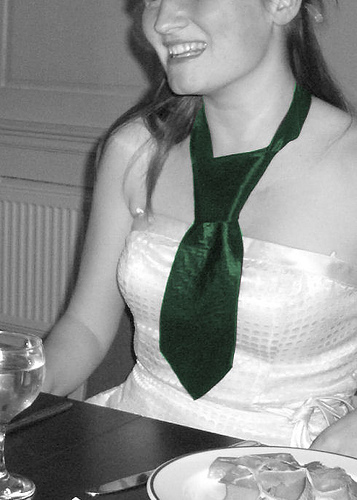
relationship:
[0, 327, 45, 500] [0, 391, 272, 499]
glass on table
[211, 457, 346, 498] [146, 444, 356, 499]
food on plate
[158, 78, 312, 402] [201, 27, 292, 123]
tie around neck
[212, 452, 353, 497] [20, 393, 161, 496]
meat on table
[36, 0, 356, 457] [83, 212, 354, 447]
female wearing a dress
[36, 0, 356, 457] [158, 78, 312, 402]
female wearing a tie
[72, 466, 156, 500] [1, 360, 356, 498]
butter knife on table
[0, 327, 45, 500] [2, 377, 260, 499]
glass on table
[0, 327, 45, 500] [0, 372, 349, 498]
glass on table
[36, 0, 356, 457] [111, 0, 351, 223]
female with hair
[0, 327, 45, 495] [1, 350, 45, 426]
glass of water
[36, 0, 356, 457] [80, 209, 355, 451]
female wearing a white dress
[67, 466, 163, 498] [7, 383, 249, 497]
butter knife on table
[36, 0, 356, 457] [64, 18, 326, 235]
female has hair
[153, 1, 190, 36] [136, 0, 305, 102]
nose on face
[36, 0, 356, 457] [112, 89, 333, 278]
female wearing tie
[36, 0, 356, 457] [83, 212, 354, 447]
female wearing dress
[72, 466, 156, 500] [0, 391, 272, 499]
butter knife on table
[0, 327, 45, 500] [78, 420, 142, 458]
glass on table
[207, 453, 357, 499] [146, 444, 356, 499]
food on plate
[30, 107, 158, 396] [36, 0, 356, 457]
arm on female